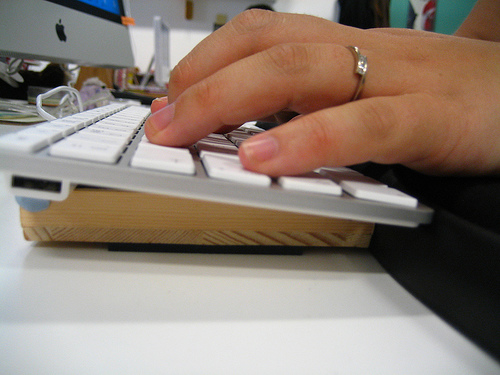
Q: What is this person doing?
A: Typing.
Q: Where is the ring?
A: On her hand.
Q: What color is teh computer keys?
A: White.